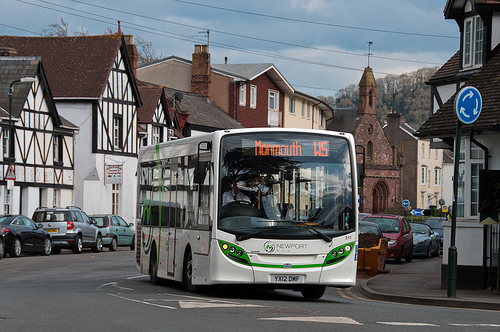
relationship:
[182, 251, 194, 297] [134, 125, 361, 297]
wheel on bus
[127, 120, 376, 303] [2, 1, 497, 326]
bus traveling village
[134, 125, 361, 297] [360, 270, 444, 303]
bus turning at corner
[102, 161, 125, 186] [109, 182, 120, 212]
sign hanging by door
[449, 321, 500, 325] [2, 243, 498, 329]
markings on street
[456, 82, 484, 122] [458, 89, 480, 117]
sign with lines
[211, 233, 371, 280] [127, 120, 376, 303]
lines on bus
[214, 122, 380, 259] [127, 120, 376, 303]
windscreen in bus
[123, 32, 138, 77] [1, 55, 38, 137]
chimney on roof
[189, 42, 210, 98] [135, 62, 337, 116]
chimney on roof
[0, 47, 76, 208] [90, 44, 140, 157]
building with trim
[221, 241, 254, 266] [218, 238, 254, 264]
headlight in panel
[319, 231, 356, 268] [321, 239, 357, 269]
headlight in panel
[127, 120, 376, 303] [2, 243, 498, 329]
bus on street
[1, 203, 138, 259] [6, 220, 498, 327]
cars on street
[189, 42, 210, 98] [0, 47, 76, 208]
chimney on building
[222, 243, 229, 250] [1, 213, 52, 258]
headlight on cars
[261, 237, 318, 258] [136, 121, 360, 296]
name on bus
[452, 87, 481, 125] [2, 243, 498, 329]
sign on street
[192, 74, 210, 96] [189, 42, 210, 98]
bricks on chimney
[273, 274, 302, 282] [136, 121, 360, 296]
license plate on bus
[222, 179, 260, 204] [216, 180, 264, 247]
driver behind wheel